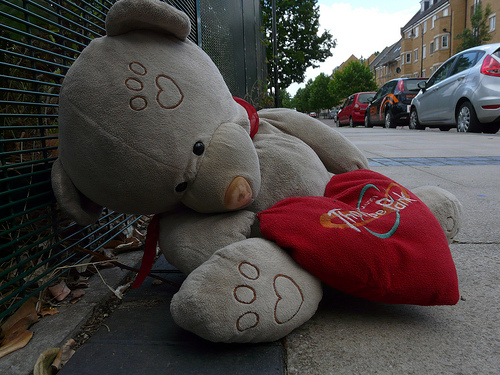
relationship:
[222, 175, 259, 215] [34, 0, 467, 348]
nose on bear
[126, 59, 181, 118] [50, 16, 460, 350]
paw print on bear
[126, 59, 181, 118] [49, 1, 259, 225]
paw print on head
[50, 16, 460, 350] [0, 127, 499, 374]
bear on sidewalk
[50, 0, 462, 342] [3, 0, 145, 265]
bear in front door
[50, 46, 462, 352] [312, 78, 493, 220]
teddy bear on sidewalk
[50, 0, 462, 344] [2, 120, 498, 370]
teddy bear on ground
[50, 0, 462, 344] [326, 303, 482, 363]
teddy bear on sidewalk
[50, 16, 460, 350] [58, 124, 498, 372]
bear on sidewalk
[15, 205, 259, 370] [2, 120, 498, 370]
debris on ground